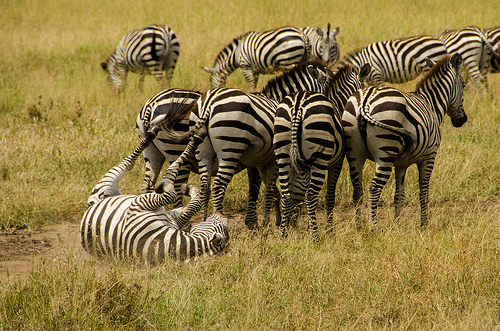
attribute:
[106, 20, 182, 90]
zebra — eating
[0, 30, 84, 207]
grass — green, dry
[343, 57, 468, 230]
zebra — striped